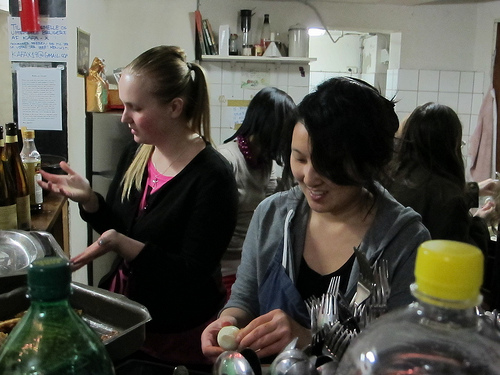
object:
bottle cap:
[26, 256, 76, 287]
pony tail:
[118, 62, 213, 204]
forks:
[314, 292, 338, 333]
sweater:
[77, 136, 242, 354]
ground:
[410, 160, 435, 200]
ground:
[439, 119, 457, 141]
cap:
[411, 239, 485, 302]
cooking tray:
[4, 280, 154, 372]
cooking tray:
[0, 230, 70, 288]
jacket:
[215, 181, 435, 355]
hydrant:
[19, 0, 39, 34]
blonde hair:
[117, 38, 215, 203]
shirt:
[107, 156, 171, 294]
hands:
[234, 309, 312, 364]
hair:
[293, 77, 398, 216]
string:
[280, 209, 295, 281]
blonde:
[35, 43, 240, 360]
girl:
[199, 75, 429, 365]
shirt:
[294, 251, 357, 317]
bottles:
[19, 130, 45, 214]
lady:
[214, 86, 296, 303]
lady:
[390, 101, 499, 298]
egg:
[217, 325, 241, 349]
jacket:
[467, 88, 498, 198]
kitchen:
[0, 0, 500, 375]